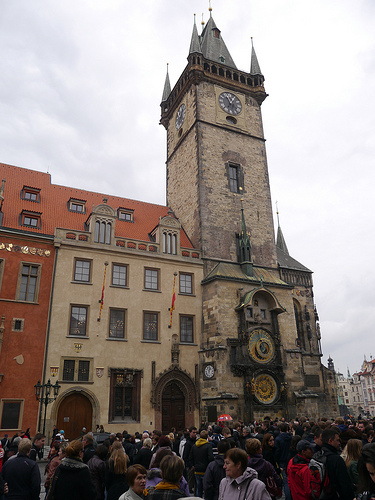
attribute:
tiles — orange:
[41, 185, 65, 227]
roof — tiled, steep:
[0, 161, 198, 259]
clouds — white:
[0, 1, 373, 378]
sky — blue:
[0, 0, 373, 377]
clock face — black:
[216, 88, 241, 118]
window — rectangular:
[141, 264, 161, 292]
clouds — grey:
[35, 48, 141, 150]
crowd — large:
[21, 429, 364, 485]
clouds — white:
[269, 17, 359, 148]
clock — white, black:
[216, 90, 243, 116]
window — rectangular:
[139, 308, 169, 343]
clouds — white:
[46, 50, 104, 136]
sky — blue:
[17, 25, 136, 168]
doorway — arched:
[148, 368, 202, 428]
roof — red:
[2, 162, 214, 275]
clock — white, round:
[217, 89, 241, 116]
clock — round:
[174, 104, 187, 127]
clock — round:
[245, 326, 275, 362]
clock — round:
[254, 373, 277, 405]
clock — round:
[202, 365, 213, 380]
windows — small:
[145, 266, 165, 293]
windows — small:
[109, 261, 128, 288]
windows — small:
[69, 299, 91, 334]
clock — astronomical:
[241, 318, 277, 371]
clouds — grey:
[280, 19, 374, 169]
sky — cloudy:
[268, 9, 360, 260]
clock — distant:
[199, 360, 219, 381]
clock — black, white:
[218, 92, 243, 115]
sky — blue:
[0, 0, 346, 171]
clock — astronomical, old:
[231, 330, 287, 375]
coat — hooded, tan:
[217, 456, 258, 497]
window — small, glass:
[70, 200, 80, 211]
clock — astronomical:
[215, 87, 247, 120]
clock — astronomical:
[173, 102, 188, 126]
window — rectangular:
[220, 157, 241, 195]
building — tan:
[24, 146, 172, 365]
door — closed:
[134, 371, 191, 432]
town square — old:
[2, 418, 373, 498]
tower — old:
[159, 0, 281, 270]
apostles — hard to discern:
[236, 326, 280, 344]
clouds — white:
[61, 1, 173, 128]